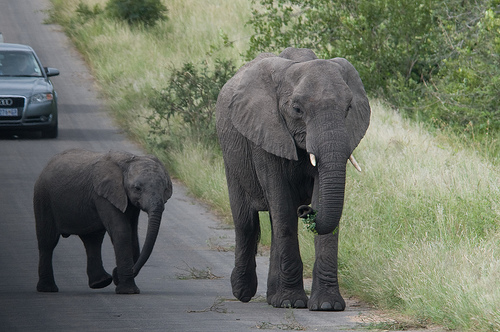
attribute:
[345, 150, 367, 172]
tusk — white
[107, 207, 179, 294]
trunk — gray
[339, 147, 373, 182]
tusk — white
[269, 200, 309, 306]
leg — gray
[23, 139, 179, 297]
elephant — baby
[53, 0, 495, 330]
grass — tall, light green, dead, strewn 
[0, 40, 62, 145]
car — Audi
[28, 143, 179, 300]
baby — gray, african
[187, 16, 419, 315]
elephant — smaller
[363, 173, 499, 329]
grass — tall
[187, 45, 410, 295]
elephant tusk — white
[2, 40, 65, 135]
car — gray, Audi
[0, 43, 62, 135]
car — Audi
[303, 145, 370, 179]
tusks — white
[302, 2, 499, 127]
bush — green, short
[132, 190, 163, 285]
trunk — wet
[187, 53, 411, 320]
elephant — Bigger 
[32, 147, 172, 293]
elephant — young, smaller, gray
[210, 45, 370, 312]
elephant — large, gray, African, grey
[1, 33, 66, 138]
audi car — shiny, silver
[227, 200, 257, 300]
leg — gray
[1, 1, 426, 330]
road — grey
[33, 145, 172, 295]
elephants — grey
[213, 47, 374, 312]
elephants — grey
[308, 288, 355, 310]
toes — grey, curved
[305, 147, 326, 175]
tusks — white